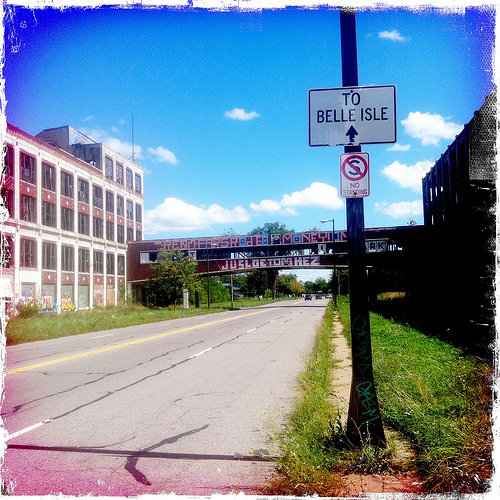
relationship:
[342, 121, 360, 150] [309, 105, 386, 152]
arrow on a sign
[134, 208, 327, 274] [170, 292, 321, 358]
bridge over street